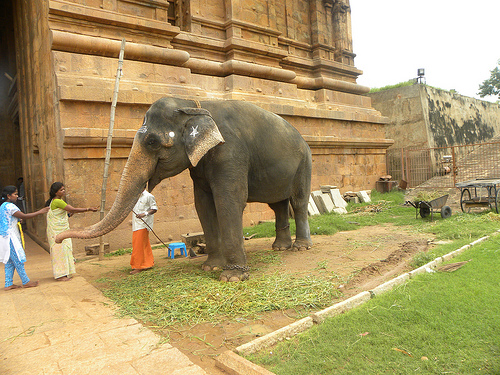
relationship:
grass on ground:
[265, 249, 495, 368] [199, 246, 496, 357]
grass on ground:
[325, 243, 482, 345] [224, 257, 495, 355]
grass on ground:
[265, 249, 495, 368] [169, 202, 498, 364]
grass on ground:
[139, 240, 339, 349] [94, 191, 487, 357]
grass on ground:
[107, 260, 265, 341] [132, 210, 428, 358]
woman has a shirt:
[19, 130, 101, 304] [44, 193, 84, 223]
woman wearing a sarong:
[45, 182, 98, 281] [36, 190, 96, 260]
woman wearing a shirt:
[0, 158, 44, 324] [0, 191, 40, 252]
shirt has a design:
[0, 191, 40, 252] [0, 190, 40, 274]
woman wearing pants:
[0, 185, 50, 291] [0, 226, 42, 288]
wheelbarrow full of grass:
[382, 160, 468, 244] [396, 163, 453, 239]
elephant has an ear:
[67, 84, 359, 280] [165, 99, 228, 178]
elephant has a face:
[67, 84, 359, 280] [109, 88, 193, 197]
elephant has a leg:
[54, 96, 312, 282] [182, 193, 340, 297]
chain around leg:
[172, 216, 351, 291] [182, 193, 340, 297]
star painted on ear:
[185, 120, 215, 150] [173, 108, 225, 167]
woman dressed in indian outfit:
[0, 185, 50, 291] [0, 144, 38, 300]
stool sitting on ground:
[148, 219, 207, 280] [58, 170, 267, 322]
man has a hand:
[104, 141, 183, 323] [112, 204, 162, 229]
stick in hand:
[131, 205, 203, 266] [112, 204, 162, 229]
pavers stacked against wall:
[259, 163, 410, 256] [48, 0, 398, 230]